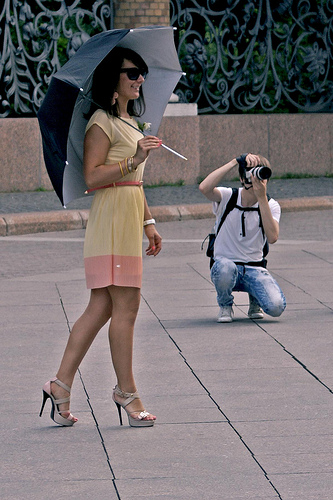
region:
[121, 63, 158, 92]
Black sunglasses on woman's face.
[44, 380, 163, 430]
Woman wearing high heels.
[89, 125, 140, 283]
Woman wearing yellow and pink dress.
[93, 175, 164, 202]
Pink belt on woman's waist.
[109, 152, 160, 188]
Bracelets around woman's wrist.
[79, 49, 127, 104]
Woman has dark hair.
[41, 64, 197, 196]
Woman is holding umbrella.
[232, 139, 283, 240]
Person holding camera to face.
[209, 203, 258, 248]
Person wearing white shirt.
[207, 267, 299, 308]
Person wearing blue jeans.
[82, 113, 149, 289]
A yellow and pink short sleeved dress.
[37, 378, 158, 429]
A pair of beige high heels.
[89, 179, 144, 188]
A pink belt.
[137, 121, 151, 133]
A white flower.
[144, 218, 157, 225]
A white band.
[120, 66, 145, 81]
A black pair of sunglasses.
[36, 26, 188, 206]
A black umbrella.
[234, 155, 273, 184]
A black and white camera.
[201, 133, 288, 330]
A guy bent down taking a picture.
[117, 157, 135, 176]
Bracelets.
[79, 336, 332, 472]
Smoothly paved concrete walkway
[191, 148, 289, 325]
Photographer striking a pose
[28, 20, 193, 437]
Lady walking on the pavement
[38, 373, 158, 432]
Feet in high heeled shoes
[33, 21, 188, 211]
Black, unfurled umbrella held at a slanted ange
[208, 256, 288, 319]
Pair of faded jeans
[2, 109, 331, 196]
Low concrete wall part of a fence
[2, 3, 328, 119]
Styled metal frame forming part of a wall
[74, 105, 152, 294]
Light yelow/brown dress with a pink bottom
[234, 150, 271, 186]
Camera held at an eye level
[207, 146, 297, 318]
a man holding a camera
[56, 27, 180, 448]
a woman holding an umbrella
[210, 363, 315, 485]
grey stone tiles of the ground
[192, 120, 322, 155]
tan concrete wall in the background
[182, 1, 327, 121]
iron fence on a concrete wall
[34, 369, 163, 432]
the woman's strappy sandals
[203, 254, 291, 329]
the man's blue jeans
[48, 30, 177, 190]
a woman wearing sunglasses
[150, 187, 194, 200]
grey stones of the sidewalk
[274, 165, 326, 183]
grass growing along the edge of the wall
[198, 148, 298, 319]
a man squatting down to take a photo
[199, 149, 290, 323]
the man is taking a picture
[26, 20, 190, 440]
a woman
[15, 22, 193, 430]
the woman with the umbrella is wearing high heels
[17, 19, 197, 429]
the woman holds the umbrella with one hand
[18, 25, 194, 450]
the woman holds a black umbrella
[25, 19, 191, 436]
the woman with the umbrella is smiling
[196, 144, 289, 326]
the man taking a photo is wearing a backpack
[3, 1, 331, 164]
a wall with a wrought iron fence is behind the people